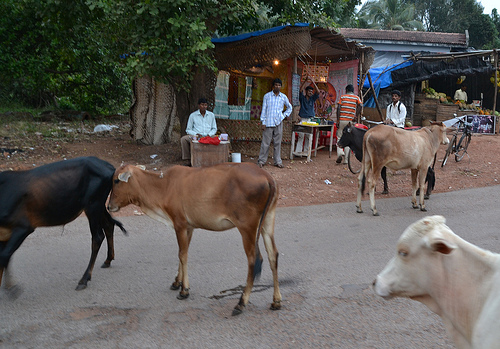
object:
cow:
[1, 154, 129, 302]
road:
[0, 184, 499, 348]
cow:
[106, 160, 282, 316]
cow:
[355, 121, 451, 218]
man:
[178, 97, 218, 164]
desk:
[190, 133, 230, 166]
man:
[256, 77, 293, 169]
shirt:
[260, 92, 294, 128]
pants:
[257, 121, 284, 167]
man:
[454, 83, 469, 104]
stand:
[413, 85, 500, 134]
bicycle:
[440, 113, 473, 168]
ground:
[1, 118, 498, 216]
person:
[294, 72, 322, 161]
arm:
[298, 74, 309, 98]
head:
[304, 85, 315, 97]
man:
[335, 84, 364, 167]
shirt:
[337, 93, 362, 123]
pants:
[336, 119, 355, 164]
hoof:
[176, 288, 192, 300]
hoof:
[169, 283, 180, 290]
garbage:
[93, 123, 117, 134]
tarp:
[389, 55, 494, 90]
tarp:
[356, 61, 415, 110]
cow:
[371, 215, 500, 348]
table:
[289, 122, 334, 164]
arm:
[284, 97, 293, 117]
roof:
[205, 22, 376, 65]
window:
[227, 73, 248, 107]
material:
[213, 68, 254, 122]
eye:
[398, 248, 409, 258]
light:
[273, 59, 280, 66]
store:
[176, 20, 376, 159]